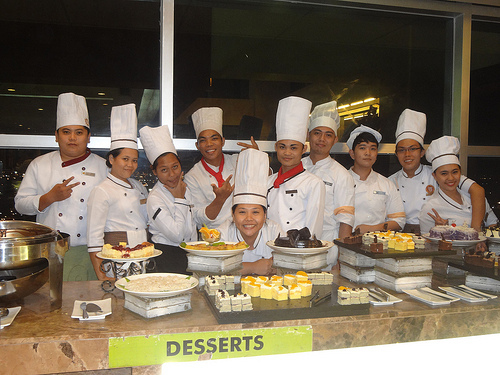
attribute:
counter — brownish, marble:
[3, 280, 499, 372]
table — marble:
[2, 268, 499, 373]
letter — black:
[165, 342, 180, 355]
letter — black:
[184, 340, 192, 355]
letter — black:
[193, 339, 204, 353]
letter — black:
[206, 337, 216, 353]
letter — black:
[219, 338, 229, 352]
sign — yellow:
[107, 326, 314, 372]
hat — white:
[221, 146, 283, 207]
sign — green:
[110, 320, 325, 374]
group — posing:
[32, 52, 490, 300]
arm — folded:
[8, 170, 83, 225]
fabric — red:
[272, 160, 305, 186]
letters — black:
[164, 335, 264, 357]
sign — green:
[107, 323, 315, 369]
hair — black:
[358, 138, 370, 142]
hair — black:
[107, 152, 114, 158]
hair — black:
[155, 154, 165, 157]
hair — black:
[80, 126, 90, 133]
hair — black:
[230, 204, 237, 213]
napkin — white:
[72, 297, 112, 321]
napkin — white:
[362, 282, 401, 307]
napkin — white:
[401, 285, 462, 310]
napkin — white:
[438, 280, 498, 306]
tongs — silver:
[306, 285, 333, 312]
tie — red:
[194, 156, 228, 192]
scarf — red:
[271, 165, 306, 185]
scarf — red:
[202, 158, 228, 185]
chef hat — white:
[53, 93, 88, 128]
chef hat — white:
[106, 101, 139, 151]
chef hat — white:
[137, 125, 174, 157]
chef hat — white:
[185, 102, 222, 139]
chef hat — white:
[233, 153, 268, 207]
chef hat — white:
[277, 95, 307, 148]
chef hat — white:
[311, 101, 338, 138]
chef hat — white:
[425, 132, 460, 165]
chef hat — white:
[394, 105, 426, 147]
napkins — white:
[339, 280, 499, 305]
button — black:
[75, 196, 86, 203]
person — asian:
[220, 205, 280, 272]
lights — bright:
[336, 93, 382, 127]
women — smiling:
[241, 124, 312, 299]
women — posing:
[61, 90, 331, 268]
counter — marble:
[188, 284, 215, 326]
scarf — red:
[201, 157, 225, 189]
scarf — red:
[202, 154, 229, 186]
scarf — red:
[274, 161, 308, 190]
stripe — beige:
[334, 203, 355, 216]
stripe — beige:
[386, 208, 404, 218]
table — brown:
[0, 238, 498, 373]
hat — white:
[53, 90, 92, 131]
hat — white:
[107, 101, 140, 152]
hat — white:
[138, 123, 180, 163]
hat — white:
[190, 103, 227, 141]